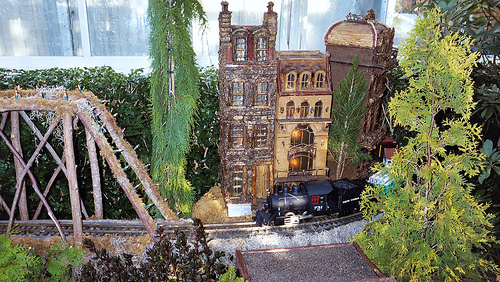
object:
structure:
[0, 85, 183, 250]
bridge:
[0, 87, 182, 250]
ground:
[16, 223, 408, 280]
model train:
[251, 177, 372, 227]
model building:
[217, 0, 400, 210]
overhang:
[1, 84, 183, 249]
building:
[218, 0, 401, 215]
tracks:
[1, 210, 383, 238]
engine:
[251, 135, 403, 227]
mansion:
[217, 0, 400, 210]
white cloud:
[12, 8, 137, 40]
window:
[316, 73, 324, 88]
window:
[301, 74, 309, 89]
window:
[286, 73, 294, 89]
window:
[286, 101, 296, 117]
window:
[301, 101, 310, 117]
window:
[314, 100, 324, 118]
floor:
[259, 233, 386, 257]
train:
[251, 136, 403, 228]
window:
[233, 32, 248, 64]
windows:
[255, 82, 271, 109]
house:
[218, 0, 398, 217]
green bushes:
[0, 65, 220, 219]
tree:
[348, 5, 499, 280]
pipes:
[367, 160, 403, 185]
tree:
[147, 0, 209, 217]